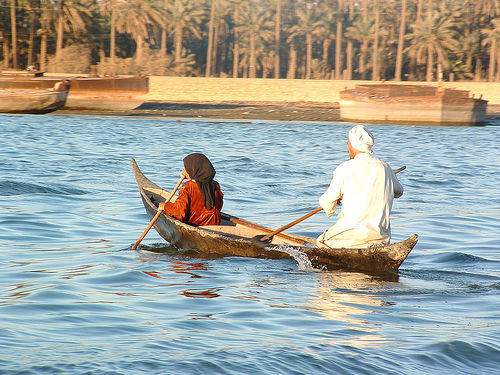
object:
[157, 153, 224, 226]
woman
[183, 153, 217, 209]
scarf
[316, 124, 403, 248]
man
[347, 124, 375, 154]
turban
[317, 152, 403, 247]
robe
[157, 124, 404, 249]
couple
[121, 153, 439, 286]
boat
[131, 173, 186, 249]
oar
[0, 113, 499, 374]
water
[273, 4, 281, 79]
palm tree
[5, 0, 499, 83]
group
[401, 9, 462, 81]
palm tree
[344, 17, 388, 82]
palm tree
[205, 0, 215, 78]
palm tree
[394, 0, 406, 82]
palm tree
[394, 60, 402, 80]
trunk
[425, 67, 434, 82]
trunk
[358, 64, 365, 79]
trunk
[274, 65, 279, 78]
trunk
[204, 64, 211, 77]
trunk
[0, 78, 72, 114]
boat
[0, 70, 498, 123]
shore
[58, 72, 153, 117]
boat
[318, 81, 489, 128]
boat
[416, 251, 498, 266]
wave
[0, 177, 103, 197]
wave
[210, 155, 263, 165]
wave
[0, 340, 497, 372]
wave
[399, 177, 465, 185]
wave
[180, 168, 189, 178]
hand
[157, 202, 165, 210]
hand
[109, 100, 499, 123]
dirt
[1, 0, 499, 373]
image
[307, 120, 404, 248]
white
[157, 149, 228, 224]
arabic dressing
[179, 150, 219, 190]
head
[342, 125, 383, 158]
head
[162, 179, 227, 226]
shirt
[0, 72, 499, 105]
sand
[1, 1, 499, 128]
background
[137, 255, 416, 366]
reflection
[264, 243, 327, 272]
splash